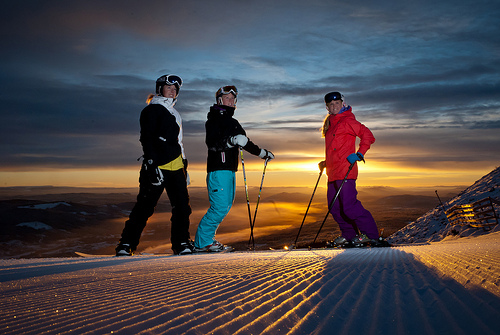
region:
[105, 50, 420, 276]
Three skiers on a hillside.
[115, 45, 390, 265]
Three women in skiing uniforms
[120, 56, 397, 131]
Three women with ski goggles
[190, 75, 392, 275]
Skiers holding ski poles.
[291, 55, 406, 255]
Female skier wearing red jacket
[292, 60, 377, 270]
Female skier wearing purple ski pants.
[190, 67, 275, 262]
Female wearing turquoise ski pants.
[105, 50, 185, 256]
Female wearing black skiing outfit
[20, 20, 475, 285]
Sunrise at a ski slope and skiers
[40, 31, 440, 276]
Female skiers standing on a ski slope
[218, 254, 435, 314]
grooming grooves on a ski trail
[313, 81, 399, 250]
a woman skiing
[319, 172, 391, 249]
purple snow pants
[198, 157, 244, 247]
light blue snow pants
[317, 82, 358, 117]
woman with ski goggles on her head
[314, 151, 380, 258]
gloved hand holding a ski pole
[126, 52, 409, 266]
women on the side of a mountain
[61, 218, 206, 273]
snowboard on the trail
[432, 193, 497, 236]
fencing in the snow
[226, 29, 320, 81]
clouds in the sky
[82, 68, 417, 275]
Three people are on skies or snowboards.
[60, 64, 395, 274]
The three people are standing on a ski slope.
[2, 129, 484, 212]
The sun sets behind them.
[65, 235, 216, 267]
The woman is on a snowboard.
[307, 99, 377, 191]
The woman wears a red jacket.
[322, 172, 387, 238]
The woman wears purple pants.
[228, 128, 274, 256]
The person is holding ski poles.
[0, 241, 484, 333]
The snow is groomed.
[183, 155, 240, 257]
The person wears blue pants.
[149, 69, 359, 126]
The three people wear helmets.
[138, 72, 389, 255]
Three people are seen.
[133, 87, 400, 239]
Sunset or sunrise scene.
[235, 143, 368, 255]
Two people are holding skiing poles in hand.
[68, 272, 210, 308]
Snow is in ground.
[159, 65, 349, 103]
Goggles are in head.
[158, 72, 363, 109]
People wear helmet in head.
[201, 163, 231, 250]
Pant is blue in color.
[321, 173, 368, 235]
Pant is purple in color.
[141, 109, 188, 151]
Jacket is black and white in color.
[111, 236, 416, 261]
They are wearing sneakers.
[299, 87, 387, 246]
skier posing for a picture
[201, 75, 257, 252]
skier posing for a picture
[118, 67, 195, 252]
snowboarder posing for a picture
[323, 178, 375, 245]
purple ski pants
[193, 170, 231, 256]
light blue ski pants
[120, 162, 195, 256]
black ski pants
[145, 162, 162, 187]
black and white ski glove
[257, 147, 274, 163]
black and white ski glove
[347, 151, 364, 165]
bright blue ski glove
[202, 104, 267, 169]
black and white ski jacket